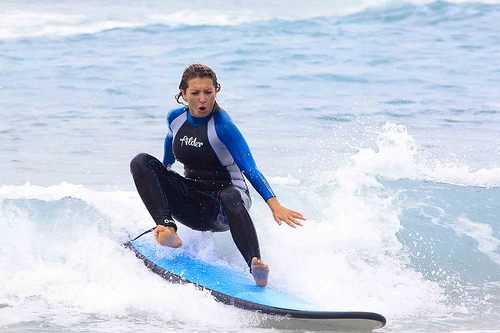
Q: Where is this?
A: This is at the ocean.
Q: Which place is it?
A: It is an ocean.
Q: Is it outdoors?
A: Yes, it is outdoors.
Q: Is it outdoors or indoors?
A: It is outdoors.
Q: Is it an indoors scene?
A: No, it is outdoors.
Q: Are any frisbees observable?
A: No, there are no frisbees.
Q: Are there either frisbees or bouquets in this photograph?
A: No, there are no frisbees or bouquets.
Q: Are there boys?
A: No, there are no boys.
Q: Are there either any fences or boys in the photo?
A: No, there are no boys or fences.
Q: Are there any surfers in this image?
A: Yes, there is a surfer.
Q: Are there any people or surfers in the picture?
A: Yes, there is a surfer.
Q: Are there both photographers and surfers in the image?
A: No, there is a surfer but no photographers.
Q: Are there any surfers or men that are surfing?
A: Yes, the surfer is surfing.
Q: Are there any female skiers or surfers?
A: Yes, there is a female surfer.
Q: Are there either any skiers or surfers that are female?
A: Yes, the surfer is female.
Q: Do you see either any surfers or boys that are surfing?
A: Yes, the surfer is surfing.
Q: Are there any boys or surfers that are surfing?
A: Yes, the surfer is surfing.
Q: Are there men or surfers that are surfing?
A: Yes, the surfer is surfing.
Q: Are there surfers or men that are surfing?
A: Yes, the surfer is surfing.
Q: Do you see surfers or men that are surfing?
A: Yes, the surfer is surfing.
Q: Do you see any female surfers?
A: Yes, there is a female surfer.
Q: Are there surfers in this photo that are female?
A: Yes, there is a surfer that is female.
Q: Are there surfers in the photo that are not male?
A: Yes, there is a female surfer.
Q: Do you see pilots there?
A: No, there are no pilots.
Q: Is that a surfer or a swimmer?
A: That is a surfer.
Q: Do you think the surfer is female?
A: Yes, the surfer is female.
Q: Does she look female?
A: Yes, the surfer is female.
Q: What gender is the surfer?
A: The surfer is female.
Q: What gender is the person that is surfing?
A: The surfer is female.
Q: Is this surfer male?
A: No, the surfer is female.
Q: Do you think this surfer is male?
A: No, the surfer is female.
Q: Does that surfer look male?
A: No, the surfer is female.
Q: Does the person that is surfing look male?
A: No, the surfer is female.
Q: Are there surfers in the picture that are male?
A: No, there is a surfer but she is female.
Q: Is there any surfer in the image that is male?
A: No, there is a surfer but she is female.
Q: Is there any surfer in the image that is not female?
A: No, there is a surfer but she is female.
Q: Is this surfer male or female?
A: The surfer is female.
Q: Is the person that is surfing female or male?
A: The surfer is female.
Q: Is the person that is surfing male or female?
A: The surfer is female.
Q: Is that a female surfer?
A: Yes, that is a female surfer.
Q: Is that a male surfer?
A: No, that is a female surfer.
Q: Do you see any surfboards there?
A: Yes, there is a surfboard.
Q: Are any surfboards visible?
A: Yes, there is a surfboard.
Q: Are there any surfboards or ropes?
A: Yes, there is a surfboard.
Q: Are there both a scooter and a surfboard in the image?
A: No, there is a surfboard but no scooters.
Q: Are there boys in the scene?
A: No, there are no boys.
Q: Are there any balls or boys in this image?
A: No, there are no boys or balls.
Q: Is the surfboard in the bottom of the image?
A: Yes, the surfboard is in the bottom of the image.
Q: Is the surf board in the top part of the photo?
A: No, the surf board is in the bottom of the image.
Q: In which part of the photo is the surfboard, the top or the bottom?
A: The surfboard is in the bottom of the image.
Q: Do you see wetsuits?
A: Yes, there is a wetsuit.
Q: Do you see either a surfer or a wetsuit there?
A: Yes, there is a wetsuit.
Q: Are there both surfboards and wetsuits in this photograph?
A: Yes, there are both a wetsuit and a surfboard.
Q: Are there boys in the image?
A: No, there are no boys.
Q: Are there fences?
A: No, there are no fences.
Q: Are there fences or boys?
A: No, there are no fences or boys.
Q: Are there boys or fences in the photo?
A: No, there are no fences or boys.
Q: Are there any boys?
A: No, there are no boys.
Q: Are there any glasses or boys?
A: No, there are no boys or glasses.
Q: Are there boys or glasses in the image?
A: No, there are no boys or glasses.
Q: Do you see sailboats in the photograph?
A: No, there are no sailboats.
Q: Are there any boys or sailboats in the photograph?
A: No, there are no sailboats or boys.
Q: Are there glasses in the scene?
A: No, there are no glasses.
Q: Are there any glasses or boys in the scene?
A: No, there are no glasses or boys.